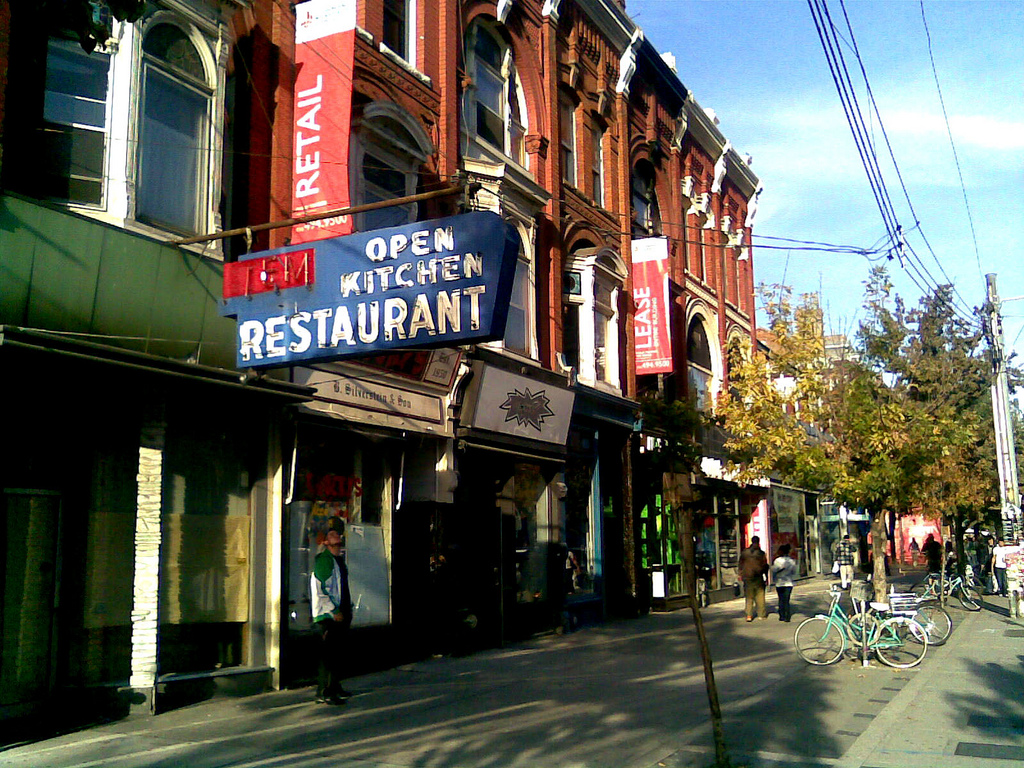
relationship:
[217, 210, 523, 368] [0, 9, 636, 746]
sign on building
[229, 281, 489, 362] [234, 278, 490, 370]
word on sign